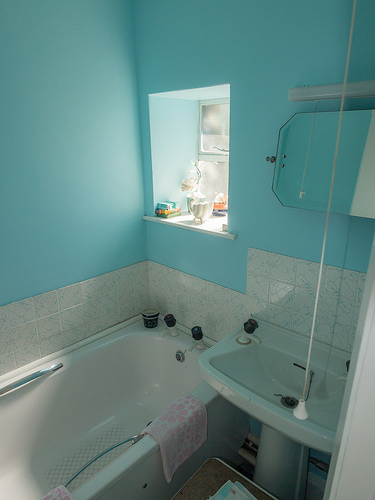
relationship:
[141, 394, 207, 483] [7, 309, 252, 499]
towel on side of bathtub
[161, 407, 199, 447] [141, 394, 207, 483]
flowers on towel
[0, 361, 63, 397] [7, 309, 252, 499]
handle on side of bathtub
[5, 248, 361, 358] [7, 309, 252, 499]
tile around bathtub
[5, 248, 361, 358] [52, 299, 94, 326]
tile has swirls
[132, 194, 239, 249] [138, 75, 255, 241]
shelving on window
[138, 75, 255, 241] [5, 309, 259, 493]
window above tub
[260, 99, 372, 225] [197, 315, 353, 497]
mirror above sink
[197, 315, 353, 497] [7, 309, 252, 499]
sink near bathtub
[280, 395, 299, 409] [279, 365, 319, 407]
drain attached with chain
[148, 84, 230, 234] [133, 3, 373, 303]
window in wall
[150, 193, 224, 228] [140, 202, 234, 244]
shampoos on sill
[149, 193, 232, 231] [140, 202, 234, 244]
toys on sill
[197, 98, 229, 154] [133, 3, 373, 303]
mirror on wall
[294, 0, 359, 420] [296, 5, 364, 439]
cord for closing blinds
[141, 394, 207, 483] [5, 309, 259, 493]
towel on side of tub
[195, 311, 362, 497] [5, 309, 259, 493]
sink near tub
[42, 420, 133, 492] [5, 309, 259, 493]
ledge on tub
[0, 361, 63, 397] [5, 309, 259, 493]
handle on tub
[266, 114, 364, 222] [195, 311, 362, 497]
cabinet over sink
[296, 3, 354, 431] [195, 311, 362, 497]
cord near sink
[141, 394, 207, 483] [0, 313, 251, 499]
towel hanging over side of bathtub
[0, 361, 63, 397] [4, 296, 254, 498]
handle in tub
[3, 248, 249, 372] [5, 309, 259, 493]
wall around tub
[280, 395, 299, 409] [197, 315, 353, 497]
drain in sink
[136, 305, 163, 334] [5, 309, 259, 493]
cup on side of tub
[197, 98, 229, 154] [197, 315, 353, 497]
mirror above sink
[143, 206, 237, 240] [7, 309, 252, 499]
ledge above bathtub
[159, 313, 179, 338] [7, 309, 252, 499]
faucet on bathtub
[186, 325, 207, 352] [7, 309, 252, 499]
faucet on bathtub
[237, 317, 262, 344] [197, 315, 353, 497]
faucet on sink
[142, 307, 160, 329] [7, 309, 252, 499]
cup on bathtub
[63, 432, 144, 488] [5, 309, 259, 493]
handle by tub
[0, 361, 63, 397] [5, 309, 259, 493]
handle by tub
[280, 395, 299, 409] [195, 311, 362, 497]
drain in sink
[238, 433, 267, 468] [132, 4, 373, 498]
vent against wall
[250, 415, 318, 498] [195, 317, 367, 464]
pedestal under sink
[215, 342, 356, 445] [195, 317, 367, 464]
basin in sink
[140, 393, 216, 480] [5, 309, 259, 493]
towel hanging over tub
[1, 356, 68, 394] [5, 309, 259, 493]
handle on tub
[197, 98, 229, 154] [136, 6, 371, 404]
mirror hanging on wall